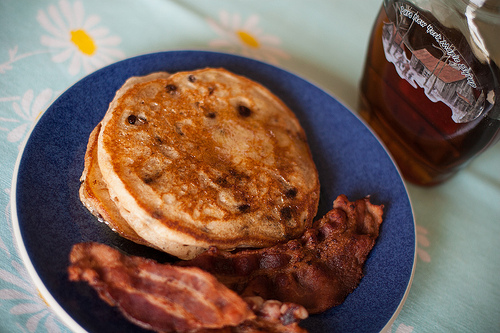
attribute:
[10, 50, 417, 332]
breakfast — scene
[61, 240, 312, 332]
slice of bacon — crisp, chewy, cooked, fat, wrinkly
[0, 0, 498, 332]
tablecloth — light blue, blue, flowered, white, floral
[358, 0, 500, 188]
maple syrup — glass bottle, bottle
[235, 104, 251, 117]
chocolate chip — brown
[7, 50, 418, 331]
blue plate — ceramic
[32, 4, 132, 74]
daisy — white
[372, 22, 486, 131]
illustration — cabin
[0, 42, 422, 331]
plate — blue